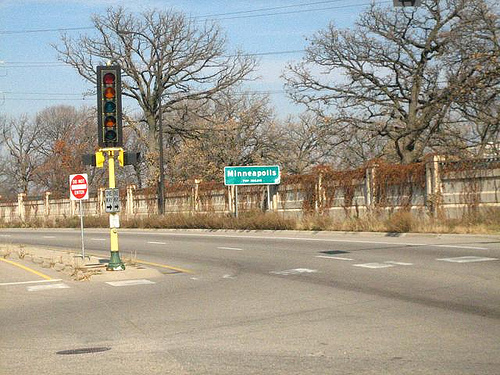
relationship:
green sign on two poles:
[222, 164, 280, 186] [230, 187, 271, 212]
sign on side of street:
[62, 172, 92, 265] [14, 212, 498, 372]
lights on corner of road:
[103, 72, 116, 142] [0, 227, 497, 373]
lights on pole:
[103, 72, 116, 142] [91, 149, 131, 279]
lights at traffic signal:
[103, 72, 116, 142] [94, 62, 124, 153]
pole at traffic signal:
[104, 151, 124, 268] [94, 65, 124, 145]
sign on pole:
[104, 188, 111, 211] [106, 150, 122, 272]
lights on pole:
[103, 72, 116, 142] [94, 145, 125, 252]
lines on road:
[139, 225, 264, 272] [0, 227, 497, 373]